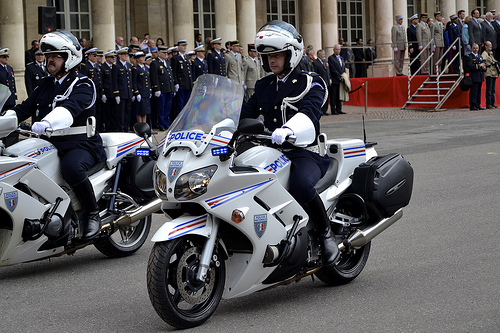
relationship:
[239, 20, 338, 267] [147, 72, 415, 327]
policeman on a motorcycle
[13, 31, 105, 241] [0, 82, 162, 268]
policeman on a motorcycle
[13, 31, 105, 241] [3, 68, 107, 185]
policeman wearing a uniform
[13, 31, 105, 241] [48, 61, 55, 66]
policeman has a mustache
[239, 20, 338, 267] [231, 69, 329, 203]
policeman wearing a uniform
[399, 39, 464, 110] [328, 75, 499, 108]
stairs leading up to platform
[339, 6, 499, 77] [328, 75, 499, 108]
people on platform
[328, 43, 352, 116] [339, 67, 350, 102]
man holding a overcoat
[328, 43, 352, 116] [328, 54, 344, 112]
man wearing a suit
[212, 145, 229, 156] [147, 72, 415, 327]
light on motorcycle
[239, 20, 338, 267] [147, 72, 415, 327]
policeman on motorcycle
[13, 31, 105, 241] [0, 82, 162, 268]
policeman on motorcycle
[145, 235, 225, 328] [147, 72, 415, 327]
tire on front of motorcycle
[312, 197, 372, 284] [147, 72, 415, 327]
tire on back of motorcycle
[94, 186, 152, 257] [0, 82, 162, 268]
tire on back of motorcycle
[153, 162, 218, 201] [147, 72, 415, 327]
headlights on motorcycle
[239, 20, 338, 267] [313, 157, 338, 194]
policeman sitting on seat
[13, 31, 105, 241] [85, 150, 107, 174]
policeman sitting on seat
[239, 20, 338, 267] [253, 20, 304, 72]
policeman wearing a helmet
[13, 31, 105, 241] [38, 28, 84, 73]
policeman wearing a helmet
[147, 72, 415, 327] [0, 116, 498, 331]
motorcycle on street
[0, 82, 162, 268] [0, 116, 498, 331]
motorcycle on street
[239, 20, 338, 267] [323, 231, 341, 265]
policeman has a foot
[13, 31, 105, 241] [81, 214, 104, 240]
policeman has a foot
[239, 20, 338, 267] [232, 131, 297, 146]
policeman holding handle bar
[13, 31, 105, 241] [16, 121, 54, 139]
policeman holding handle bar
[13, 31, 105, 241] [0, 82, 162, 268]
policeman riding a motorcycle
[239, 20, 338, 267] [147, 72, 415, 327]
policeman riding a motorcycle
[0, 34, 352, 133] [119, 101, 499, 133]
officers are on sidewalk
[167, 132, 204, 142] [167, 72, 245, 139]
word on windshield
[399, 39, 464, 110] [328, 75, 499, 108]
stairs on platform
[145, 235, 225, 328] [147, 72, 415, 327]
tire on motorcycle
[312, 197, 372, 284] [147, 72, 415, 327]
tire on motorcycle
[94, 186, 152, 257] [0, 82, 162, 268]
tire on motorcycle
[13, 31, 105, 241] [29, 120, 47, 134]
policeman wearing a glove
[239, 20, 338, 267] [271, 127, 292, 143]
policeman wearing a glove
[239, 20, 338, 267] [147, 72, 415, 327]
policeman riding on motorcycle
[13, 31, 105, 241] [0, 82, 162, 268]
policeman riding on motorcycle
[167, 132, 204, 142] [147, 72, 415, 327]
word on motorcycle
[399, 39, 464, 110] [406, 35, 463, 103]
stairs has a railing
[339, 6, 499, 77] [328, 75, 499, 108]
people standing on platform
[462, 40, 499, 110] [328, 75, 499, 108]
men standing in front of platform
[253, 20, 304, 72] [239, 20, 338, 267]
helmet on policeman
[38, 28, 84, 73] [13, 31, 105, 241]
helmet on policeman